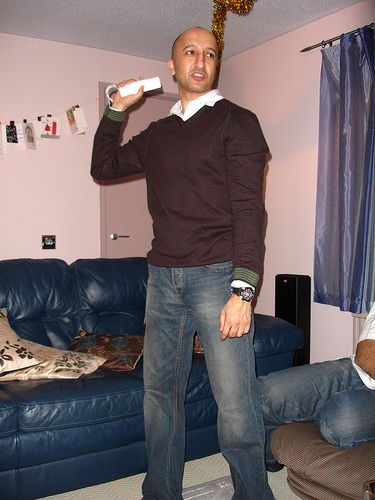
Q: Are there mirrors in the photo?
A: No, there are no mirrors.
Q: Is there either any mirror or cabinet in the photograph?
A: No, there are no mirrors or cabinets.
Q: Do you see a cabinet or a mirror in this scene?
A: No, there are no mirrors or cabinets.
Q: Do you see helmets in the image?
A: No, there are no helmets.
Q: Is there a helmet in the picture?
A: No, there are no helmets.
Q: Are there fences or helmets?
A: No, there are no helmets or fences.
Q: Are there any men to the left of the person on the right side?
A: Yes, there is a man to the left of the person.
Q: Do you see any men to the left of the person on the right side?
A: Yes, there is a man to the left of the person.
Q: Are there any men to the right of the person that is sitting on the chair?
A: No, the man is to the left of the person.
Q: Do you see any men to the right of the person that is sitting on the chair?
A: No, the man is to the left of the person.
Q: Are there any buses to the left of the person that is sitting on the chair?
A: No, there is a man to the left of the person.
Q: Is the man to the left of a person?
A: Yes, the man is to the left of a person.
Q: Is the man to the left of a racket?
A: No, the man is to the left of a person.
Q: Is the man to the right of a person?
A: No, the man is to the left of a person.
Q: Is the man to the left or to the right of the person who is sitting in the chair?
A: The man is to the left of the person.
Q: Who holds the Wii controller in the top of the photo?
A: The man holds the Wii controller.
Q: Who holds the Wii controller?
A: The man holds the Wii controller.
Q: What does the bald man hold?
A: The man holds the Wii remotes.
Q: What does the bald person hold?
A: The man holds the Wii remotes.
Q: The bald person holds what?
A: The man holds the Wii remotes.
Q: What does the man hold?
A: The man holds the Wii remotes.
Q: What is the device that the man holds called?
A: The device is a Wii controller.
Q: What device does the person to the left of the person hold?
A: The man holds the Wii remotes.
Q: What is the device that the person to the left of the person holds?
A: The device is a Wii controller.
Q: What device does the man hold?
A: The man holds the Wii remotes.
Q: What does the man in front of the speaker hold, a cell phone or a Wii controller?
A: The man holds a Wii controller.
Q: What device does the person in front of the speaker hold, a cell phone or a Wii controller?
A: The man holds a Wii controller.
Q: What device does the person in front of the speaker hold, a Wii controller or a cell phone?
A: The man holds a Wii controller.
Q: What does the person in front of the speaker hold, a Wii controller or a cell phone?
A: The man holds a Wii controller.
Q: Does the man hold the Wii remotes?
A: Yes, the man holds the Wii remotes.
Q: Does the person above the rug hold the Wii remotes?
A: Yes, the man holds the Wii remotes.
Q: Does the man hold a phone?
A: No, the man holds the Wii remotes.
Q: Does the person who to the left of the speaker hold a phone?
A: No, the man holds the Wii remotes.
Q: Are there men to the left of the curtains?
A: Yes, there is a man to the left of the curtains.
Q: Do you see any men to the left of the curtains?
A: Yes, there is a man to the left of the curtains.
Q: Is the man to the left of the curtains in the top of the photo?
A: Yes, the man is to the left of the curtains.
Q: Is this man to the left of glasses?
A: No, the man is to the left of the curtains.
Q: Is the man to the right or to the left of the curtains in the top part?
A: The man is to the left of the curtains.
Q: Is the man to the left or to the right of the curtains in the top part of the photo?
A: The man is to the left of the curtains.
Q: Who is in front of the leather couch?
A: The man is in front of the couch.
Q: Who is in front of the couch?
A: The man is in front of the couch.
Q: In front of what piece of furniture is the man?
A: The man is in front of the couch.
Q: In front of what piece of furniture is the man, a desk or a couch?
A: The man is in front of a couch.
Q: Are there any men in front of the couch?
A: Yes, there is a man in front of the couch.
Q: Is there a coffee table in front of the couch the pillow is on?
A: No, there is a man in front of the couch.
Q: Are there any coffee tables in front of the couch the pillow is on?
A: No, there is a man in front of the couch.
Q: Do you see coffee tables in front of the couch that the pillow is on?
A: No, there is a man in front of the couch.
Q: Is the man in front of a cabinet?
A: No, the man is in front of the couch.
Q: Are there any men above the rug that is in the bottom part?
A: Yes, there is a man above the rug.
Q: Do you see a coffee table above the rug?
A: No, there is a man above the rug.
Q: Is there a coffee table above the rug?
A: No, there is a man above the rug.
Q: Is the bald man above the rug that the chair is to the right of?
A: Yes, the man is above the rug.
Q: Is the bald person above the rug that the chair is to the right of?
A: Yes, the man is above the rug.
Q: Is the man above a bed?
A: No, the man is above the rug.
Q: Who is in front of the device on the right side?
A: The man is in front of the speaker.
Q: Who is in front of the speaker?
A: The man is in front of the speaker.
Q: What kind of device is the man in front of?
A: The man is in front of the speaker.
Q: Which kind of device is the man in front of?
A: The man is in front of the speaker.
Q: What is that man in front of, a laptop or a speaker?
A: The man is in front of a speaker.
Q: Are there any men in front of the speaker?
A: Yes, there is a man in front of the speaker.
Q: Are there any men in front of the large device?
A: Yes, there is a man in front of the speaker.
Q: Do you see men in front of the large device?
A: Yes, there is a man in front of the speaker.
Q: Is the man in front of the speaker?
A: Yes, the man is in front of the speaker.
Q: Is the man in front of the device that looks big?
A: Yes, the man is in front of the speaker.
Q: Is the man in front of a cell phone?
A: No, the man is in front of the speaker.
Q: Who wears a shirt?
A: The man wears a shirt.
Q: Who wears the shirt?
A: The man wears a shirt.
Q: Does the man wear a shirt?
A: Yes, the man wears a shirt.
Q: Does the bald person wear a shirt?
A: Yes, the man wears a shirt.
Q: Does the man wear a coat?
A: No, the man wears a shirt.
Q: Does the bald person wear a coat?
A: No, the man wears a shirt.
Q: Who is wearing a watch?
A: The man is wearing a watch.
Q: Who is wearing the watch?
A: The man is wearing a watch.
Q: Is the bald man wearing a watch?
A: Yes, the man is wearing a watch.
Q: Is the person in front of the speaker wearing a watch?
A: Yes, the man is wearing a watch.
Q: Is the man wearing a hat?
A: No, the man is wearing a watch.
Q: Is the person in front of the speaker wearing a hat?
A: No, the man is wearing a watch.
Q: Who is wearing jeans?
A: The man is wearing jeans.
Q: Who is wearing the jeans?
A: The man is wearing jeans.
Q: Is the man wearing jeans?
A: Yes, the man is wearing jeans.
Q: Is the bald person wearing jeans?
A: Yes, the man is wearing jeans.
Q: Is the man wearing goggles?
A: No, the man is wearing jeans.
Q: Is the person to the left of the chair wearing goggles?
A: No, the man is wearing jeans.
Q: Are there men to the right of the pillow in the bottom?
A: Yes, there is a man to the right of the pillow.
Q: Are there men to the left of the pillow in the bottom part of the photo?
A: No, the man is to the right of the pillow.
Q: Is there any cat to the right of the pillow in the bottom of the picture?
A: No, there is a man to the right of the pillow.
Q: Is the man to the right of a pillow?
A: Yes, the man is to the right of a pillow.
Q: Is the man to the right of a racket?
A: No, the man is to the right of a pillow.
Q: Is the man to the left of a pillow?
A: No, the man is to the right of a pillow.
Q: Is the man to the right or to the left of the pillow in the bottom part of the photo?
A: The man is to the right of the pillow.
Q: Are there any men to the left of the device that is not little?
A: Yes, there is a man to the left of the speaker.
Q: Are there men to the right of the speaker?
A: No, the man is to the left of the speaker.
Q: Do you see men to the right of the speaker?
A: No, the man is to the left of the speaker.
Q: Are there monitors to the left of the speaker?
A: No, there is a man to the left of the speaker.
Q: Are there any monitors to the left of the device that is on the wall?
A: No, there is a man to the left of the speaker.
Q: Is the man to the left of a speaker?
A: Yes, the man is to the left of a speaker.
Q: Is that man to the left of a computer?
A: No, the man is to the left of a speaker.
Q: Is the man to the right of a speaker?
A: No, the man is to the left of a speaker.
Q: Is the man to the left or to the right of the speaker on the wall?
A: The man is to the left of the speaker.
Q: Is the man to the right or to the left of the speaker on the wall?
A: The man is to the left of the speaker.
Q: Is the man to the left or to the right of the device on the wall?
A: The man is to the left of the speaker.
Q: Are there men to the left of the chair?
A: Yes, there is a man to the left of the chair.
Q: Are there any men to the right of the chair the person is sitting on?
A: No, the man is to the left of the chair.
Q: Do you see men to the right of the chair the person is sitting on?
A: No, the man is to the left of the chair.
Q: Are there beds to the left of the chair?
A: No, there is a man to the left of the chair.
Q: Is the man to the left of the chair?
A: Yes, the man is to the left of the chair.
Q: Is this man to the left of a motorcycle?
A: No, the man is to the left of the chair.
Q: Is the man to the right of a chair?
A: No, the man is to the left of a chair.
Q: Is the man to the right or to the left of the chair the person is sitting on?
A: The man is to the left of the chair.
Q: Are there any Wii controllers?
A: Yes, there is a Wii controller.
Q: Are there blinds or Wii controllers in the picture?
A: Yes, there is a Wii controller.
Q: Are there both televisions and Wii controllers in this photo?
A: No, there is a Wii controller but no televisions.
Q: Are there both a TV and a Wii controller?
A: No, there is a Wii controller but no televisions.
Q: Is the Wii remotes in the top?
A: Yes, the Wii remotes is in the top of the image.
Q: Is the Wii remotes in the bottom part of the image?
A: No, the Wii remotes is in the top of the image.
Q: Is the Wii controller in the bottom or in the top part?
A: The Wii controller is in the top of the image.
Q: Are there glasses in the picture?
A: No, there are no glasses.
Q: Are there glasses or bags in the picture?
A: No, there are no glasses or bags.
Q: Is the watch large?
A: Yes, the watch is large.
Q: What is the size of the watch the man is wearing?
A: The watch is large.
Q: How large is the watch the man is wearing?
A: The watch is large.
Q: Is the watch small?
A: No, the watch is large.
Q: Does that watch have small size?
A: No, the watch is large.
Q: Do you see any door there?
A: Yes, there is a door.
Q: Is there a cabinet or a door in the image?
A: Yes, there is a door.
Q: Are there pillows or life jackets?
A: Yes, there is a pillow.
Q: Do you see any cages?
A: No, there are no cages.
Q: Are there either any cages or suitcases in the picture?
A: No, there are no cages or suitcases.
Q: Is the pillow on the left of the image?
A: Yes, the pillow is on the left of the image.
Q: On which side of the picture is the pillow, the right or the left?
A: The pillow is on the left of the image.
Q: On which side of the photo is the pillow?
A: The pillow is on the left of the image.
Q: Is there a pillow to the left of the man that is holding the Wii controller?
A: Yes, there is a pillow to the left of the man.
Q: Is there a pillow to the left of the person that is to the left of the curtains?
A: Yes, there is a pillow to the left of the man.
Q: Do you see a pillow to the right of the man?
A: No, the pillow is to the left of the man.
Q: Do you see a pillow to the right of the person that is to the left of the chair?
A: No, the pillow is to the left of the man.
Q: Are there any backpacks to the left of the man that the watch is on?
A: No, there is a pillow to the left of the man.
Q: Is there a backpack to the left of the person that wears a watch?
A: No, there is a pillow to the left of the man.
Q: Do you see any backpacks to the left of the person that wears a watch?
A: No, there is a pillow to the left of the man.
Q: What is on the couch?
A: The pillow is on the couch.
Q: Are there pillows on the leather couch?
A: Yes, there is a pillow on the couch.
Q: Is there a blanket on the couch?
A: No, there is a pillow on the couch.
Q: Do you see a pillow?
A: Yes, there is a pillow.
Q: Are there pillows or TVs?
A: Yes, there is a pillow.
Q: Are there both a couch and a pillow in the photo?
A: Yes, there are both a pillow and a couch.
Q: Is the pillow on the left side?
A: Yes, the pillow is on the left of the image.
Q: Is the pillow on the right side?
A: No, the pillow is on the left of the image.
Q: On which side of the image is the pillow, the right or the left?
A: The pillow is on the left of the image.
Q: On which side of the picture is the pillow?
A: The pillow is on the left of the image.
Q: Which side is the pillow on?
A: The pillow is on the left of the image.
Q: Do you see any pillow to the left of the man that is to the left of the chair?
A: Yes, there is a pillow to the left of the man.